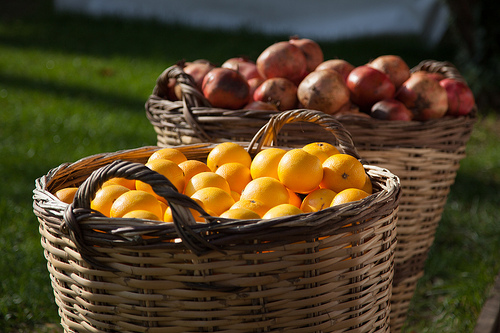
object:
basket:
[143, 57, 483, 333]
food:
[51, 140, 377, 227]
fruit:
[52, 141, 377, 229]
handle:
[67, 160, 212, 251]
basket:
[28, 108, 404, 333]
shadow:
[0, 63, 144, 113]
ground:
[0, 13, 500, 333]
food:
[164, 34, 476, 124]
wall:
[53, 0, 446, 49]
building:
[40, 0, 458, 53]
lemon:
[277, 148, 323, 195]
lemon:
[204, 140, 253, 173]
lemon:
[109, 188, 164, 218]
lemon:
[148, 147, 188, 163]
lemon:
[319, 152, 367, 191]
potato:
[345, 65, 397, 109]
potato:
[256, 40, 308, 83]